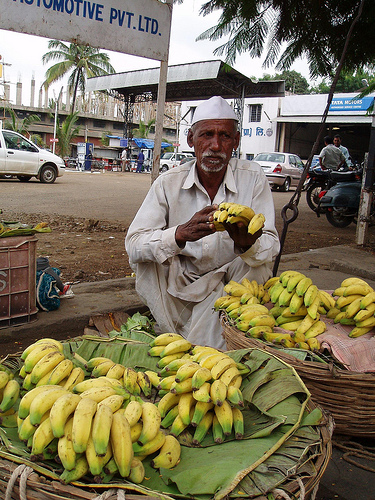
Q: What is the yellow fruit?
A: Banana.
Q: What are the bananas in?
A: Basket.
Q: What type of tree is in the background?
A: Palm.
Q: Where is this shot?
A: Roadside vendor.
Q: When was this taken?
A: Daytime.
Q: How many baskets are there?
A: 2.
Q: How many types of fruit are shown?
A: 1.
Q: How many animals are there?
A: 0.